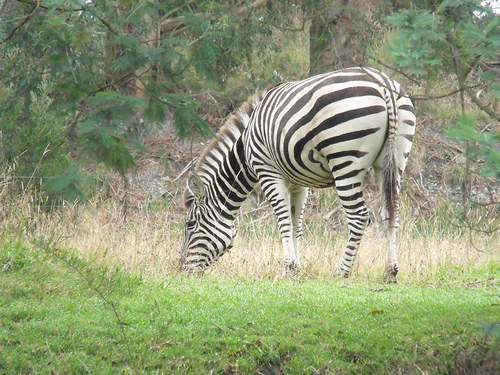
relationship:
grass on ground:
[36, 114, 488, 355] [35, 190, 479, 359]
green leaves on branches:
[2, 2, 498, 202] [1, 0, 498, 137]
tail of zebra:
[376, 81, 404, 243] [175, 73, 415, 275]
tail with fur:
[382, 86, 404, 244] [380, 144, 400, 233]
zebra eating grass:
[184, 61, 474, 278] [129, 236, 464, 341]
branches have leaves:
[84, 13, 123, 45] [9, 2, 169, 172]